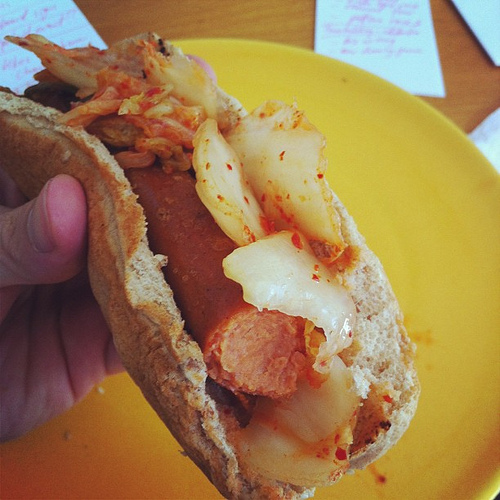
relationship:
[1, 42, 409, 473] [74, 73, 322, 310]
hot dog with sauce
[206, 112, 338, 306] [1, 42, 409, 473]
vegetables on hot dog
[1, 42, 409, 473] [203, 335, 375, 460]
hot dog has been eaten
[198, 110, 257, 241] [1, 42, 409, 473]
cucumber on hot dog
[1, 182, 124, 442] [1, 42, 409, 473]
hand holding hot dog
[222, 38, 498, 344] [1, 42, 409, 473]
dish under hot dog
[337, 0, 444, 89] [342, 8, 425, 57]
paper with writing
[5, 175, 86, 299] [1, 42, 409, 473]
thumb grabbing hot dog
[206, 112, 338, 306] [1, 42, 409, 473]
vegetables below hot dog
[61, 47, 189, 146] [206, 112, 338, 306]
spices over vegetables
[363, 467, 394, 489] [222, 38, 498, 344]
spot on dish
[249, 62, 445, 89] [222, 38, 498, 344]
edge of dish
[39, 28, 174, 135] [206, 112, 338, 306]
ketchup on onion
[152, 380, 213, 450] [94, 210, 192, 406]
piece of bread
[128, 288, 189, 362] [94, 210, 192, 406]
edge of bread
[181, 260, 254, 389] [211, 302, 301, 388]
outer edge of sausage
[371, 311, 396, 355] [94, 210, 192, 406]
holes in bread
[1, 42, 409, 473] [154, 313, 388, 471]
hot dog in bun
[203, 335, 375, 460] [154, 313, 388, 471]
bite out of bun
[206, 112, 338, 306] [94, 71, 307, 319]
onion on top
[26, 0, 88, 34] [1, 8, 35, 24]
paper with writing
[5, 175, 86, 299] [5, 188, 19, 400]
thumb on side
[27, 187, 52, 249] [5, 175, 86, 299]
nail on thumb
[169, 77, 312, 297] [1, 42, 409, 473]
onion on hot dog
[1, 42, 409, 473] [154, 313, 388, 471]
hot dog on bun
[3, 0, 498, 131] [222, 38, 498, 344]
table under dish